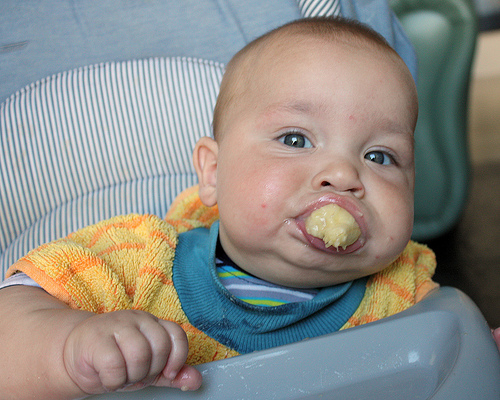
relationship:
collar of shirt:
[177, 242, 205, 290] [90, 233, 173, 314]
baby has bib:
[0, 15, 438, 397] [4, 185, 440, 369]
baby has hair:
[0, 15, 438, 397] [206, 17, 421, 141]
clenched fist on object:
[68, 310, 202, 395] [79, 285, 499, 398]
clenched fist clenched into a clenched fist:
[68, 310, 202, 395] [68, 310, 202, 395]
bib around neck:
[4, 185, 440, 369] [181, 220, 391, 319]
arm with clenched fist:
[6, 227, 214, 397] [66, 307, 205, 399]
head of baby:
[195, 15, 421, 287] [0, 15, 438, 397]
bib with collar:
[4, 180, 458, 362] [173, 219, 371, 354]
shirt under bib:
[241, 293, 337, 330] [4, 180, 458, 362]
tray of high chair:
[428, 279, 440, 391] [7, 26, 491, 397]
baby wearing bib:
[0, 15, 438, 397] [13, 213, 445, 365]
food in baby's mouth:
[303, 203, 364, 249] [295, 197, 376, 256]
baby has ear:
[0, 15, 438, 397] [193, 134, 217, 206]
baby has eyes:
[0, 15, 438, 397] [272, 123, 403, 169]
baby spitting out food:
[0, 15, 438, 397] [287, 187, 381, 262]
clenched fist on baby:
[68, 310, 202, 395] [0, 15, 438, 397]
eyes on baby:
[268, 113, 415, 171] [173, 9, 455, 288]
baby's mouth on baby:
[286, 192, 367, 254] [139, 11, 472, 362]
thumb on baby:
[159, 362, 209, 393] [19, 9, 401, 361]